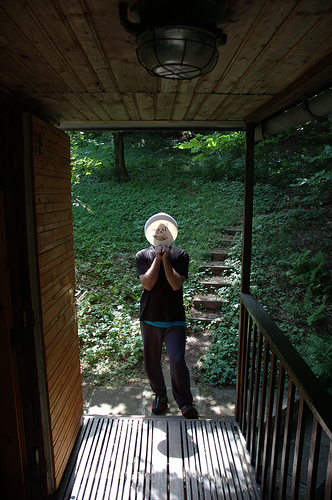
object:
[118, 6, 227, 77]
light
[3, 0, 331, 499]
porch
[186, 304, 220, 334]
steps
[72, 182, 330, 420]
hill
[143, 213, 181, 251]
frisbee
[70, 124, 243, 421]
edge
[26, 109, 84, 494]
wall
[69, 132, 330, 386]
covering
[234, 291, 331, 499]
railing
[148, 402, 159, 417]
wearing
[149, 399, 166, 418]
shoes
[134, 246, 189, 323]
shirt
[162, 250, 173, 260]
hands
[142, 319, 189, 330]
undershirt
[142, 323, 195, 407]
jeans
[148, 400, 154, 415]
orange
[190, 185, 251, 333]
path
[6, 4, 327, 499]
building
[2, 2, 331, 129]
ceiling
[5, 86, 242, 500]
doorway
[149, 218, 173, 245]
colors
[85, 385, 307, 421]
sidewalk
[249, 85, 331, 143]
gutter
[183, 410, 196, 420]
sole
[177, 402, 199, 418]
shoe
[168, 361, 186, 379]
part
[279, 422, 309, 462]
part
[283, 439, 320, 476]
dish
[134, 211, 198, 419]
boy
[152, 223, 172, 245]
face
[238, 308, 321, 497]
porch railing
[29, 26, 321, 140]
roof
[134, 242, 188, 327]
t shirt